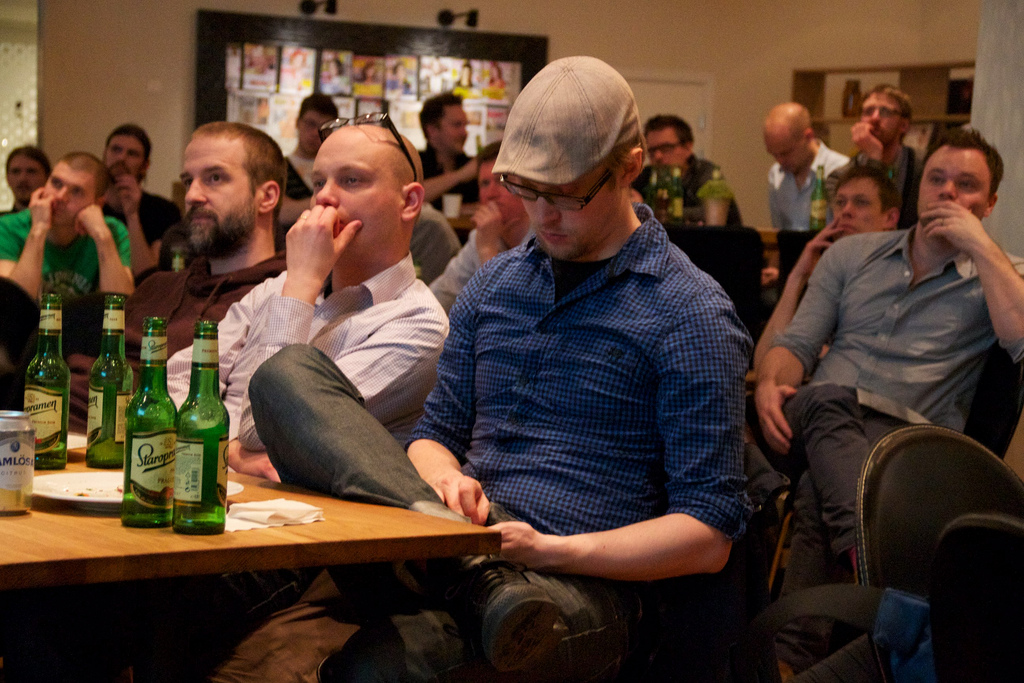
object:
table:
[0, 421, 504, 582]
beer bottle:
[121, 317, 178, 529]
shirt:
[403, 204, 752, 543]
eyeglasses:
[500, 167, 613, 210]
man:
[67, 123, 287, 436]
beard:
[183, 193, 255, 259]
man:
[0, 150, 133, 307]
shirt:
[0, 210, 133, 310]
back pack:
[765, 583, 881, 681]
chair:
[854, 424, 1024, 590]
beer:
[0, 410, 35, 513]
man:
[755, 127, 1022, 601]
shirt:
[766, 225, 1023, 434]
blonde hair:
[191, 121, 286, 223]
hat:
[491, 56, 641, 185]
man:
[217, 56, 754, 682]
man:
[163, 111, 451, 482]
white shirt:
[168, 251, 451, 473]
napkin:
[224, 498, 326, 532]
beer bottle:
[172, 320, 230, 534]